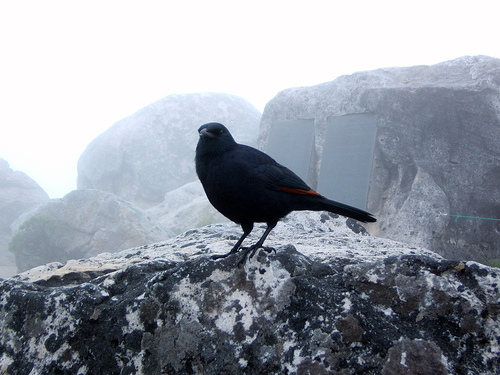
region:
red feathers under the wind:
[283, 183, 315, 196]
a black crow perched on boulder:
[182, 117, 359, 265]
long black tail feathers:
[324, 192, 384, 227]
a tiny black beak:
[200, 128, 210, 136]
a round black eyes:
[214, 123, 228, 136]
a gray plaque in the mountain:
[324, 112, 394, 209]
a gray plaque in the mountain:
[266, 117, 317, 188]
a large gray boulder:
[76, 85, 256, 182]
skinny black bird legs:
[224, 230, 276, 257]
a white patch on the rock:
[214, 302, 243, 332]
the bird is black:
[152, 83, 353, 284]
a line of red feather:
[254, 169, 339, 206]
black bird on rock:
[182, 116, 359, 257]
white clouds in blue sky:
[37, 69, 78, 92]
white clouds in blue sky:
[343, 23, 365, 53]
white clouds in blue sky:
[139, 72, 177, 97]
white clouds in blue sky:
[85, 124, 138, 165]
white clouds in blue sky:
[309, 145, 355, 168]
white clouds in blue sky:
[342, 111, 400, 131]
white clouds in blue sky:
[415, 56, 481, 130]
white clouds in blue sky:
[321, 61, 374, 122]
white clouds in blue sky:
[37, 83, 114, 148]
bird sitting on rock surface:
[0, 0, 496, 374]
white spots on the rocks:
[0, 238, 498, 373]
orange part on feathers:
[264, 184, 331, 205]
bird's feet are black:
[202, 242, 288, 267]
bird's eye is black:
[202, 123, 228, 141]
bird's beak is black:
[190, 121, 218, 146]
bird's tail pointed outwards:
[298, 201, 388, 248]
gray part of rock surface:
[133, 318, 242, 373]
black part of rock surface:
[276, 248, 425, 336]